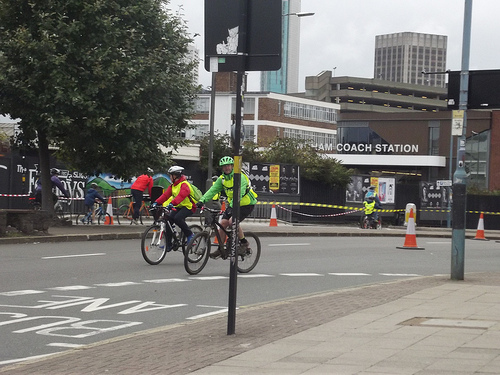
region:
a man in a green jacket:
[183, 157, 259, 274]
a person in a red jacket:
[155, 165, 195, 227]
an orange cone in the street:
[399, 202, 424, 252]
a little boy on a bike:
[68, 177, 115, 228]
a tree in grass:
[0, 0, 189, 243]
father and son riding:
[363, 180, 383, 229]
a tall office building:
[371, 27, 446, 110]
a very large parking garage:
[296, 69, 449, 124]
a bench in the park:
[0, 201, 37, 236]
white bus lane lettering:
[0, 289, 171, 348]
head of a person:
[212, 145, 242, 178]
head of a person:
[160, 159, 186, 190]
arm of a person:
[142, 182, 172, 211]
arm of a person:
[170, 187, 200, 208]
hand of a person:
[143, 200, 170, 216]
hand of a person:
[159, 205, 179, 216]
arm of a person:
[195, 175, 236, 210]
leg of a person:
[203, 212, 237, 259]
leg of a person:
[226, 210, 251, 249]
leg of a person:
[120, 184, 150, 214]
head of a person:
[206, 152, 248, 179]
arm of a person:
[145, 185, 167, 210]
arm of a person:
[170, 185, 207, 211]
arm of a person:
[195, 179, 232, 207]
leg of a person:
[210, 202, 235, 253]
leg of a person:
[230, 205, 262, 242]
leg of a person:
[172, 208, 194, 232]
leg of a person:
[136, 190, 147, 210]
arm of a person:
[54, 170, 76, 192]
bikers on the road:
[105, 159, 284, 281]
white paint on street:
[2, 264, 119, 338]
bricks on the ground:
[267, 304, 325, 334]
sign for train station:
[285, 130, 434, 163]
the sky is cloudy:
[339, 6, 362, 41]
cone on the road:
[265, 206, 286, 230]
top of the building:
[362, 27, 440, 82]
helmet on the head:
[161, 162, 183, 175]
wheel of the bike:
[177, 230, 212, 285]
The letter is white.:
[333, 138, 344, 152]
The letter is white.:
[342, 140, 352, 153]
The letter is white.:
[349, 140, 358, 155]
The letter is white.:
[355, 136, 365, 157]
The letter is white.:
[363, 140, 373, 156]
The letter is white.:
[373, 140, 383, 155]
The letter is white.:
[380, 140, 388, 154]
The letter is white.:
[384, 140, 395, 155]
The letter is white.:
[392, 139, 400, 156]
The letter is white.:
[410, 140, 420, 153]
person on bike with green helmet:
[191, 145, 274, 230]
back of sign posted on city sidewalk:
[201, 0, 287, 75]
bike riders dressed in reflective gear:
[138, 154, 264, 277]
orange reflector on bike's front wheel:
[142, 243, 151, 254]